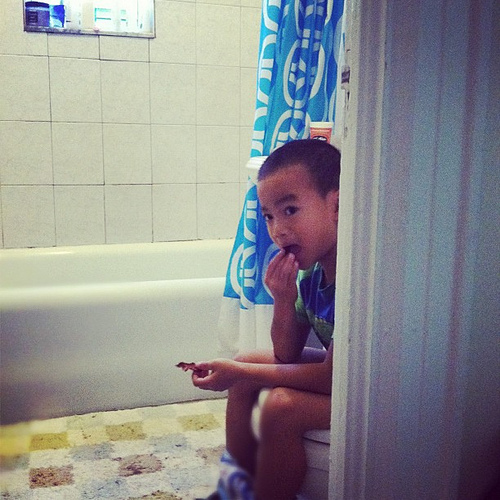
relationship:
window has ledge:
[20, 1, 157, 38] [20, 23, 159, 39]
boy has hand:
[191, 139, 340, 499] [188, 356, 237, 393]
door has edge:
[327, 2, 391, 499] [327, 1, 366, 499]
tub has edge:
[2, 237, 240, 426] [2, 238, 239, 262]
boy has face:
[191, 139, 340, 499] [257, 182, 323, 269]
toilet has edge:
[257, 391, 333, 499] [305, 440, 329, 473]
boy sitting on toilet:
[191, 139, 340, 499] [257, 391, 333, 499]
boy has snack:
[191, 139, 340, 499] [174, 361, 205, 376]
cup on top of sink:
[306, 119, 333, 146] [245, 153, 268, 189]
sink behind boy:
[245, 153, 268, 189] [191, 139, 340, 499]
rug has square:
[1, 396, 229, 499] [28, 466, 77, 489]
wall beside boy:
[458, 6, 497, 497] [191, 139, 340, 499]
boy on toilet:
[191, 139, 340, 499] [257, 391, 333, 499]